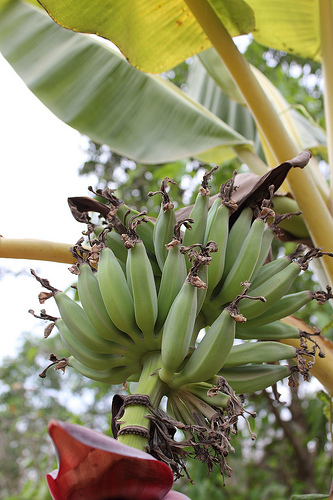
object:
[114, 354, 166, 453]
stem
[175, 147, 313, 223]
dried leaf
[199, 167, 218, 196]
objects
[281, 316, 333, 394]
vine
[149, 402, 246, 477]
branches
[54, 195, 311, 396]
banana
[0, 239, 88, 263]
stem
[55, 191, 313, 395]
fruit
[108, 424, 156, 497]
bottom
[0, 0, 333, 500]
tree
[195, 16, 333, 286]
branches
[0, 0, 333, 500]
plant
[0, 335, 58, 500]
leaves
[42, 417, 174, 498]
leaf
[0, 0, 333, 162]
leaf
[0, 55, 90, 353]
sky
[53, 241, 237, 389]
cluster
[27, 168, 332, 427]
bunches